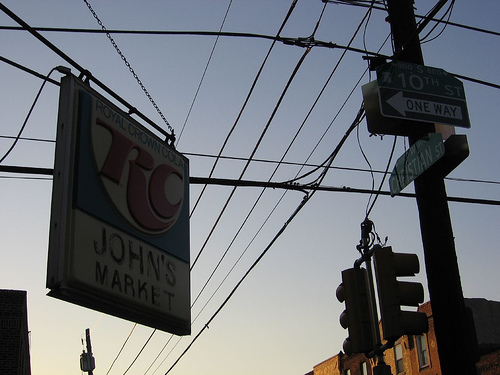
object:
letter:
[96, 118, 175, 230]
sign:
[47, 74, 191, 335]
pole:
[384, 0, 477, 373]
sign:
[376, 66, 472, 128]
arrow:
[386, 91, 462, 120]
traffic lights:
[373, 247, 428, 341]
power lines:
[237, 45, 311, 180]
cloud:
[272, 232, 333, 353]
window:
[415, 335, 430, 369]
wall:
[0, 288, 31, 375]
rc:
[96, 118, 183, 231]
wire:
[0, 165, 500, 206]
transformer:
[277, 37, 337, 48]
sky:
[0, 0, 499, 221]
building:
[1, 291, 31, 374]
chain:
[82, 0, 174, 133]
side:
[306, 0, 499, 375]